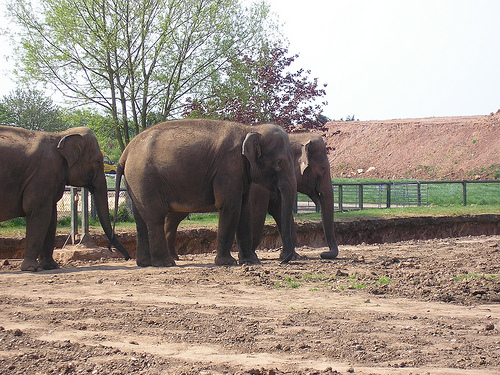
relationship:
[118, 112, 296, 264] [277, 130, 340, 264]
elephant standing with an elephant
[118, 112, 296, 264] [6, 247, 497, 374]
elephant standing in dirt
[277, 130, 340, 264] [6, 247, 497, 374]
elephant standing in dirt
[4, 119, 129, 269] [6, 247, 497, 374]
elephant standing in dirt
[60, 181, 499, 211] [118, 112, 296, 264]
fence behind elephant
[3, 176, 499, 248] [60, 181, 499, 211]
grass around fence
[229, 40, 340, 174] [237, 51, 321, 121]
tree with leaves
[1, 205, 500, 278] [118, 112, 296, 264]
ditch behind elephant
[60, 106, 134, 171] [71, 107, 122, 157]
tree with leaves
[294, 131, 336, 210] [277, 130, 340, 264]
head of elephant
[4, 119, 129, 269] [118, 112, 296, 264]
elephant behind elephant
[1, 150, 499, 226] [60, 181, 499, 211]
pasture beyond fence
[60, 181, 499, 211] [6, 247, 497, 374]
fence around dirt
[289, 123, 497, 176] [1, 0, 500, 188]
dirt hill in background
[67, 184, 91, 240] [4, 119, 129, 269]
posts behind elephant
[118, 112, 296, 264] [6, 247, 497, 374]
elephant standing on dirt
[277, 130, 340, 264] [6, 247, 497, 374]
elephant standing on dirt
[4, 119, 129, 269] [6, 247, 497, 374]
elephant standing on dirt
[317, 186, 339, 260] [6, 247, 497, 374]
trunk on dirt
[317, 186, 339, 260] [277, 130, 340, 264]
trunk of elephant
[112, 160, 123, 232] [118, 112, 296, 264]
tail of elephant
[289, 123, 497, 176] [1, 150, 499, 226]
dirt hill above pasture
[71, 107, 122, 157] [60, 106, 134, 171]
leaves on tree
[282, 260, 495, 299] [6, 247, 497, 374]
grass in dirt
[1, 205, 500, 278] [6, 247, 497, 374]
ditch in dirt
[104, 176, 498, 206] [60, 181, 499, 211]
poles on fence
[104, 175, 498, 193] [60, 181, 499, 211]
rail on fence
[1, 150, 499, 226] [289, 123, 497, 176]
pasture on side of dirt hill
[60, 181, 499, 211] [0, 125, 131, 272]
fence around elephant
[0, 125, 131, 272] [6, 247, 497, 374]
elephant standing in dirt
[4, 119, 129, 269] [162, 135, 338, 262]
elephant standing with elephant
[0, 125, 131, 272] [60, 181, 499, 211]
elephant surround by fence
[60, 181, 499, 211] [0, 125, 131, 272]
fence behind elephant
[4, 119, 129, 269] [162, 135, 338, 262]
elephant behind elephant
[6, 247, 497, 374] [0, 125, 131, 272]
dirt under elephant